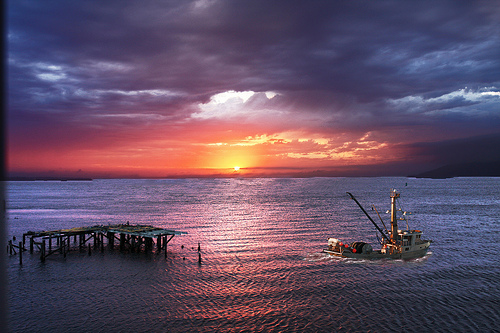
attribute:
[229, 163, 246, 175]
sun — setting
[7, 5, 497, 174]
sky — purple, very cloudy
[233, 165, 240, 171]
sun — orange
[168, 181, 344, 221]
water — orange, blue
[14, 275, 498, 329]
water — blue, orange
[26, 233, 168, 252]
support — wooden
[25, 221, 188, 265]
platform — metallic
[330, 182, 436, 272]
boat — moving